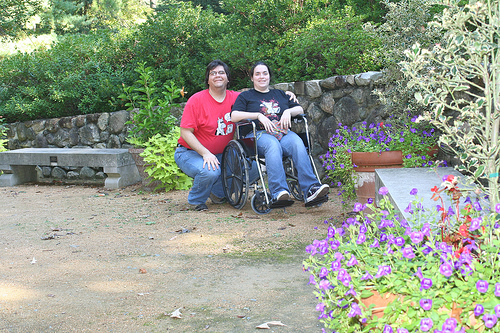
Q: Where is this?
A: This is at the backyard.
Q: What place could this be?
A: It is a backyard.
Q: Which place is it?
A: It is a backyard.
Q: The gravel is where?
A: The gravel is in the backyard.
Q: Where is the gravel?
A: The gravel is in the backyard.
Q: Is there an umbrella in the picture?
A: No, there are no umbrellas.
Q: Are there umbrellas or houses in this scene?
A: No, there are no umbrellas or houses.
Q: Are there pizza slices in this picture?
A: No, there are no pizza slices.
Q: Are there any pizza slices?
A: No, there are no pizza slices.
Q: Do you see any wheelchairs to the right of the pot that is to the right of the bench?
A: Yes, there is a wheelchair to the right of the pot.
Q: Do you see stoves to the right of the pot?
A: No, there is a wheelchair to the right of the pot.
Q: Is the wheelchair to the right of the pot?
A: Yes, the wheelchair is to the right of the pot.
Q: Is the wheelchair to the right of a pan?
A: No, the wheelchair is to the right of the pot.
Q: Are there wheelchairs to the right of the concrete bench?
A: Yes, there is a wheelchair to the right of the bench.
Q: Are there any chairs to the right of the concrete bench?
A: No, there is a wheelchair to the right of the bench.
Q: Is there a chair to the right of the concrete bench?
A: No, there is a wheelchair to the right of the bench.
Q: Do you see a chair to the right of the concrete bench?
A: No, there is a wheelchair to the right of the bench.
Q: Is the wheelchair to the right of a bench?
A: Yes, the wheelchair is to the right of a bench.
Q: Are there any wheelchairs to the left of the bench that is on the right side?
A: Yes, there is a wheelchair to the left of the bench.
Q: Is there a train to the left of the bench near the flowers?
A: No, there is a wheelchair to the left of the bench.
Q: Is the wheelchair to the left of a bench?
A: Yes, the wheelchair is to the left of a bench.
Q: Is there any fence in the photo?
A: No, there are no fences.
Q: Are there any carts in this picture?
A: No, there are no carts.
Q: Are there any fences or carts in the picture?
A: No, there are no carts or fences.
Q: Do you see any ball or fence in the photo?
A: No, there are no fences or balls.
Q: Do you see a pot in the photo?
A: Yes, there is a pot.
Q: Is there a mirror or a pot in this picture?
A: Yes, there is a pot.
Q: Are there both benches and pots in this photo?
A: Yes, there are both a pot and a bench.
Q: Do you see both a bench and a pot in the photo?
A: Yes, there are both a pot and a bench.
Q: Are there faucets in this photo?
A: No, there are no faucets.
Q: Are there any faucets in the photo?
A: No, there are no faucets.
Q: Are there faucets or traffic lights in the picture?
A: No, there are no faucets or traffic lights.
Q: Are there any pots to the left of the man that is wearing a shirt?
A: Yes, there is a pot to the left of the man.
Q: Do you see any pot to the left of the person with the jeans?
A: Yes, there is a pot to the left of the man.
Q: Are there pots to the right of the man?
A: No, the pot is to the left of the man.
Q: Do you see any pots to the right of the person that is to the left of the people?
A: No, the pot is to the left of the man.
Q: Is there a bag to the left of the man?
A: No, there is a pot to the left of the man.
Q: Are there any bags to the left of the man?
A: No, there is a pot to the left of the man.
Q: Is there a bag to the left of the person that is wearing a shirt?
A: No, there is a pot to the left of the man.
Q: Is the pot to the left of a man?
A: Yes, the pot is to the left of a man.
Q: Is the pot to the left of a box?
A: No, the pot is to the left of a man.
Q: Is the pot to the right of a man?
A: No, the pot is to the left of a man.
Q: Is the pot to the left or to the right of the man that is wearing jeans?
A: The pot is to the left of the man.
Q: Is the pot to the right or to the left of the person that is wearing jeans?
A: The pot is to the left of the man.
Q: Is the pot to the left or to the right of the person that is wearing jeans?
A: The pot is to the left of the man.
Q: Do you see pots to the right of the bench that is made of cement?
A: Yes, there is a pot to the right of the bench.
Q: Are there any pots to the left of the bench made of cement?
A: No, the pot is to the right of the bench.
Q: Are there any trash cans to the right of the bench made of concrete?
A: No, there is a pot to the right of the bench.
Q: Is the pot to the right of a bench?
A: Yes, the pot is to the right of a bench.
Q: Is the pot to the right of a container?
A: No, the pot is to the right of a bench.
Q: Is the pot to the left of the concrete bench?
A: No, the pot is to the right of the bench.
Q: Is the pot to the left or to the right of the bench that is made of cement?
A: The pot is to the right of the bench.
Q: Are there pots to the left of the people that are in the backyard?
A: Yes, there is a pot to the left of the people.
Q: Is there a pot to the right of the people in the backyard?
A: No, the pot is to the left of the people.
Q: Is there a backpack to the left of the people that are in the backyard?
A: No, there is a pot to the left of the people.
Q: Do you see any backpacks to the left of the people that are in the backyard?
A: No, there is a pot to the left of the people.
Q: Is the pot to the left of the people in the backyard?
A: Yes, the pot is to the left of the people.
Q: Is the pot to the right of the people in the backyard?
A: No, the pot is to the left of the people.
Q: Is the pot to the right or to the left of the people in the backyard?
A: The pot is to the left of the people.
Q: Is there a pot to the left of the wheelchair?
A: Yes, there is a pot to the left of the wheelchair.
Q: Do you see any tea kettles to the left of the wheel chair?
A: No, there is a pot to the left of the wheel chair.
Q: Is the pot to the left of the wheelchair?
A: Yes, the pot is to the left of the wheelchair.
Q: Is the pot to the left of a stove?
A: No, the pot is to the left of the wheelchair.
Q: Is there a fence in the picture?
A: No, there are no fences.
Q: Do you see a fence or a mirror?
A: No, there are no fences or mirrors.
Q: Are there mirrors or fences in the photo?
A: No, there are no fences or mirrors.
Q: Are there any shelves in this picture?
A: No, there are no shelves.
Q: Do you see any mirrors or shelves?
A: No, there are no shelves or mirrors.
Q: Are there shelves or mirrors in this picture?
A: No, there are no shelves or mirrors.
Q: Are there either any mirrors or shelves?
A: No, there are no shelves or mirrors.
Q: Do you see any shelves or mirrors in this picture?
A: No, there are no shelves or mirrors.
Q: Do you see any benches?
A: Yes, there is a bench.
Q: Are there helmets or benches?
A: Yes, there is a bench.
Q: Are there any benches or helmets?
A: Yes, there is a bench.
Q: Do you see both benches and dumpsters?
A: No, there is a bench but no dumpsters.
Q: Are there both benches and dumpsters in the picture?
A: No, there is a bench but no dumpsters.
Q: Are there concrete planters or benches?
A: Yes, there is a concrete bench.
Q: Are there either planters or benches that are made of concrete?
A: Yes, the bench is made of concrete.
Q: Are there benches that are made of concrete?
A: Yes, there is a bench that is made of concrete.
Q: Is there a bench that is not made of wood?
A: Yes, there is a bench that is made of cement.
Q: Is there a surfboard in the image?
A: No, there are no surfboards.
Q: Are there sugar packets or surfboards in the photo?
A: No, there are no surfboards or sugar packets.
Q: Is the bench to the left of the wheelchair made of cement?
A: Yes, the bench is made of cement.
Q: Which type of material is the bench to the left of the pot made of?
A: The bench is made of concrete.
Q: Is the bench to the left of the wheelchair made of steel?
A: No, the bench is made of concrete.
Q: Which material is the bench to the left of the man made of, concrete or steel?
A: The bench is made of concrete.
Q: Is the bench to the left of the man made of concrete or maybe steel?
A: The bench is made of concrete.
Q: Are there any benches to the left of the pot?
A: Yes, there is a bench to the left of the pot.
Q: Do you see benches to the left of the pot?
A: Yes, there is a bench to the left of the pot.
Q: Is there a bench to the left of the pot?
A: Yes, there is a bench to the left of the pot.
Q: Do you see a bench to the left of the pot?
A: Yes, there is a bench to the left of the pot.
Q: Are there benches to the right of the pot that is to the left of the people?
A: No, the bench is to the left of the pot.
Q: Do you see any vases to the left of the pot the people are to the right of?
A: No, there is a bench to the left of the pot.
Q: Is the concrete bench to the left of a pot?
A: Yes, the bench is to the left of a pot.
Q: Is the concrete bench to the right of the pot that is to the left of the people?
A: No, the bench is to the left of the pot.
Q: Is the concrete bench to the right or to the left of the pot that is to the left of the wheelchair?
A: The bench is to the left of the pot.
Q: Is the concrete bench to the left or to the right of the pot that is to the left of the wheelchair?
A: The bench is to the left of the pot.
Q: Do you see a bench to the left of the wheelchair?
A: Yes, there is a bench to the left of the wheelchair.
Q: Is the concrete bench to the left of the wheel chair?
A: Yes, the bench is to the left of the wheel chair.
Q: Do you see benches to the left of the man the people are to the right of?
A: Yes, there is a bench to the left of the man.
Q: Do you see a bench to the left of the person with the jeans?
A: Yes, there is a bench to the left of the man.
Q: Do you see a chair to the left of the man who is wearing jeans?
A: No, there is a bench to the left of the man.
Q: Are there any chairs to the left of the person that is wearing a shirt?
A: No, there is a bench to the left of the man.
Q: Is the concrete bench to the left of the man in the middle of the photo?
A: Yes, the bench is to the left of the man.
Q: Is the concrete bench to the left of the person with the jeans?
A: Yes, the bench is to the left of the man.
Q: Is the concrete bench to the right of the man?
A: No, the bench is to the left of the man.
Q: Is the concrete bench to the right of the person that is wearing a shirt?
A: No, the bench is to the left of the man.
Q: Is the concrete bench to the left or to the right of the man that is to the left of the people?
A: The bench is to the left of the man.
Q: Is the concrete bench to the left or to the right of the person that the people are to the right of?
A: The bench is to the left of the man.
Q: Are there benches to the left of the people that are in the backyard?
A: Yes, there is a bench to the left of the people.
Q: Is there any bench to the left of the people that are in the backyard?
A: Yes, there is a bench to the left of the people.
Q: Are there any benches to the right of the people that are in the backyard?
A: No, the bench is to the left of the people.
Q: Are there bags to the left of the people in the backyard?
A: No, there is a bench to the left of the people.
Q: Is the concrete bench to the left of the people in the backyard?
A: Yes, the bench is to the left of the people.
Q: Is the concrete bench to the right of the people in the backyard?
A: No, the bench is to the left of the people.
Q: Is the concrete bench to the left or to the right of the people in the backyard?
A: The bench is to the left of the people.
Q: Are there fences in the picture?
A: No, there are no fences.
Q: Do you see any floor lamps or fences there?
A: No, there are no fences or floor lamps.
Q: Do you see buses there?
A: No, there are no buses.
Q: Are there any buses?
A: No, there are no buses.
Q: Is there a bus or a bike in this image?
A: No, there are no buses or bikes.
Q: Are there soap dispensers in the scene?
A: No, there are no soap dispensers.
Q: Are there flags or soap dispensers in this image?
A: No, there are no soap dispensers or flags.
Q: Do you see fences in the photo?
A: No, there are no fences.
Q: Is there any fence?
A: No, there are no fences.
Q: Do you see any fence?
A: No, there are no fences.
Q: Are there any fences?
A: No, there are no fences.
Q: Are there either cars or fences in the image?
A: No, there are no fences or cars.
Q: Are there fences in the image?
A: No, there are no fences.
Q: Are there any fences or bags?
A: No, there are no fences or bags.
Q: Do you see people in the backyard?
A: Yes, there are people in the backyard.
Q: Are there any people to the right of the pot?
A: Yes, there are people to the right of the pot.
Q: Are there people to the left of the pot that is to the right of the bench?
A: No, the people are to the right of the pot.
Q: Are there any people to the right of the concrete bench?
A: Yes, there are people to the right of the bench.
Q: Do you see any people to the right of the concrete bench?
A: Yes, there are people to the right of the bench.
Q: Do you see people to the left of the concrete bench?
A: No, the people are to the right of the bench.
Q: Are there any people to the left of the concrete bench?
A: No, the people are to the right of the bench.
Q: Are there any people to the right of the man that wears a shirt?
A: Yes, there are people to the right of the man.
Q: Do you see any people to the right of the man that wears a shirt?
A: Yes, there are people to the right of the man.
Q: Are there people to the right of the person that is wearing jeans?
A: Yes, there are people to the right of the man.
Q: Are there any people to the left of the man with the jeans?
A: No, the people are to the right of the man.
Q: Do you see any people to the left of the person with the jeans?
A: No, the people are to the right of the man.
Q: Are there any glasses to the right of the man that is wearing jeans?
A: No, there are people to the right of the man.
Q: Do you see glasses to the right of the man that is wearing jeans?
A: No, there are people to the right of the man.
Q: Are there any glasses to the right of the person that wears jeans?
A: No, there are people to the right of the man.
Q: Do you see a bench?
A: Yes, there is a bench.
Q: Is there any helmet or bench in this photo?
A: Yes, there is a bench.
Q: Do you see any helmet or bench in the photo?
A: Yes, there is a bench.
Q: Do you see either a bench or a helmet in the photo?
A: Yes, there is a bench.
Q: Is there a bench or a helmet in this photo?
A: Yes, there is a bench.